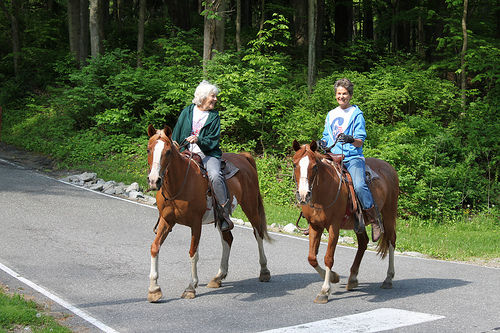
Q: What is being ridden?
A: Horses.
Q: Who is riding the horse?
A: A woman.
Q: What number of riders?
A: Two.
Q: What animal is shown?
A: Horses.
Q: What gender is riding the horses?
A: Female.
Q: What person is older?
A: The one on the left.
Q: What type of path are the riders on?
A: Paved.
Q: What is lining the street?
A: White stripe.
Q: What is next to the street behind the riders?
A: Stones.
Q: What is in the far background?
A: Trees.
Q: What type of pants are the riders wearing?
A: Blue jeans.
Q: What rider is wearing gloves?
A: The one on the right.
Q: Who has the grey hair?
A: The rider on the left.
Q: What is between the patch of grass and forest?
A: Road.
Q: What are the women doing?
A: Sitting on horses.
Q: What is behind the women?
A: Forest.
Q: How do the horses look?
A: White and brown.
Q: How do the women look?
A: Old.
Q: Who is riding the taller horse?
A: White haired woman.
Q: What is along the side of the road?
A: Rocks.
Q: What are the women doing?
A: Riding horses.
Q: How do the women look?
A: Happy.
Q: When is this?
A: Daytime.